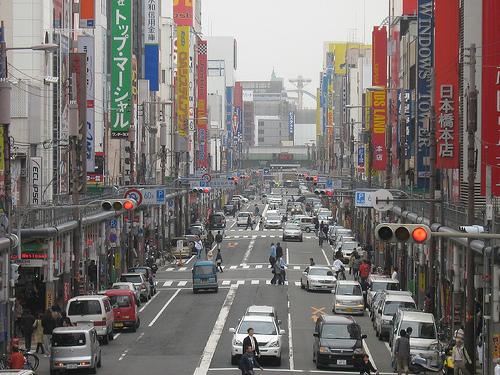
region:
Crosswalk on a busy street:
[156, 276, 319, 287]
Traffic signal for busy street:
[372, 217, 435, 249]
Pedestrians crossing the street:
[270, 255, 288, 287]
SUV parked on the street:
[390, 308, 445, 370]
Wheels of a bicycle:
[20, 350, 42, 372]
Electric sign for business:
[12, 250, 59, 264]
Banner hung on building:
[106, 0, 132, 141]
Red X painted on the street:
[307, 298, 327, 316]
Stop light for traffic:
[100, 196, 137, 215]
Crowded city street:
[262, 178, 322, 245]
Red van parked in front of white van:
[104, 286, 142, 334]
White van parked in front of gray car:
[62, 287, 119, 342]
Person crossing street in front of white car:
[241, 322, 261, 359]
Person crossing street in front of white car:
[240, 343, 262, 373]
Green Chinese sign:
[110, 0, 132, 132]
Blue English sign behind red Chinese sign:
[416, 0, 434, 182]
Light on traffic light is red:
[410, 223, 427, 243]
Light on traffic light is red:
[122, 200, 132, 211]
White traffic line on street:
[186, 278, 237, 373]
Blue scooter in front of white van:
[407, 345, 446, 374]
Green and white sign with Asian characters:
[108, 1, 133, 130]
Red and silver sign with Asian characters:
[434, 5, 458, 165]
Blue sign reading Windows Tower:
[417, 2, 432, 175]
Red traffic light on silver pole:
[373, 223, 492, 243]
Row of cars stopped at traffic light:
[232, 314, 373, 366]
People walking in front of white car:
[240, 327, 268, 372]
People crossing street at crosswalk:
[263, 240, 291, 286]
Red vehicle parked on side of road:
[108, 286, 140, 335]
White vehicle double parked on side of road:
[331, 275, 386, 321]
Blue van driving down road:
[191, 262, 221, 294]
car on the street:
[183, 256, 223, 296]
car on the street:
[221, 314, 288, 366]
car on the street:
[303, 309, 374, 369]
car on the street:
[296, 261, 338, 293]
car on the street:
[328, 276, 370, 315]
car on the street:
[49, 318, 109, 373]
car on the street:
[61, 291, 118, 342]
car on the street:
[97, 286, 143, 336]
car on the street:
[282, 221, 304, 242]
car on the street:
[233, 208, 256, 228]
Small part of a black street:
[171, 319, 201, 341]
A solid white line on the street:
[205, 326, 224, 358]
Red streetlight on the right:
[411, 225, 427, 240]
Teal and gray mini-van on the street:
[188, 260, 218, 292]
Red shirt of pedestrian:
[12, 351, 24, 368]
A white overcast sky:
[269, 17, 306, 39]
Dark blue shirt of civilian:
[243, 352, 253, 364]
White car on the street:
[306, 267, 332, 292]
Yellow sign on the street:
[222, 237, 239, 252]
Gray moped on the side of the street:
[416, 355, 443, 372]